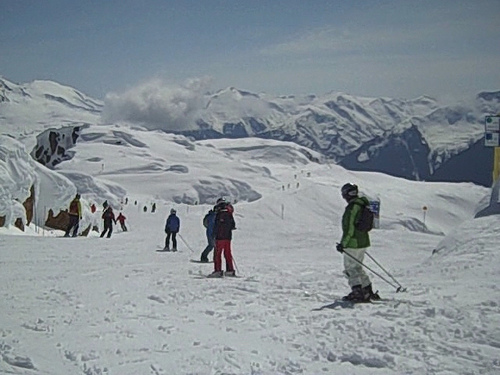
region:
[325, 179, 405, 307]
snow skier standing facing left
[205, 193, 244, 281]
skier with red pants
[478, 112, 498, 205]
sign on yellow pole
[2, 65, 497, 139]
tops of distant snowy mountains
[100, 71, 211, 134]
cloud on distant mountain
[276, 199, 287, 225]
snow trail marker stick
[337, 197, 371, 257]
two toned green winter jacket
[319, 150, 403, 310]
skier with a green suit on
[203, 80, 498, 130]
snow covered mountain range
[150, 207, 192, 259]
skier with a blue jacket on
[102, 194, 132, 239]
two skiers coming down the hill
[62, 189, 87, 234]
skier in yellow jacket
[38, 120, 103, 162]
white snow melting on side of mountain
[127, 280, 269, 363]
snow tracks from skiers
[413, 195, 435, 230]
ski lift monitor on the snow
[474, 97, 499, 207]
sign on the distance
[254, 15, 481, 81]
clouds in the sky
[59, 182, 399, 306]
skiers on the mountain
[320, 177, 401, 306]
skier wearing white pants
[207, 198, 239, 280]
skier wearing dark pink pants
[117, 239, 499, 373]
tracks in the snow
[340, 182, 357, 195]
helmet skier is wearing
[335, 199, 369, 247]
two tone green jacket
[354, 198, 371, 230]
backpack skier is wearing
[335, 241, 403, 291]
black ski poles skier is holding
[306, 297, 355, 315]
shadow on the snow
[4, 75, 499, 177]
mountains in the distance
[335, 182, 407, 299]
skier in a green jacket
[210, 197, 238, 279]
skier wearing red snowpants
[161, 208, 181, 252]
a skier wearing a blue jacket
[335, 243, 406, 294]
a skier's ski poles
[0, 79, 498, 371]
snow covered mountain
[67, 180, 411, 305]
group of skiers going down a hill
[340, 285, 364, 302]
a skier's left boot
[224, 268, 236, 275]
a skier's right boot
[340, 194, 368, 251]
The green coat the skier is wearing.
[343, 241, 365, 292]
The white pants the skier is wearing.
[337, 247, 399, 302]
The ski poles in the skier's hands on the right.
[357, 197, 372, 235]
The back pack the skier in the green coat is carrying.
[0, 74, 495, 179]
The snow covered mountains in the distance.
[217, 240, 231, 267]
The red pants the skier is wearing.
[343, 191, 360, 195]
The snow goggles the skier in the green jacket is wearing.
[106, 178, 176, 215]
The people in the distance.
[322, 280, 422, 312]
The skis the skier in the green coat is standing on.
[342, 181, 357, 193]
The helmet the skier in the green coat is wearing.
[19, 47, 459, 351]
Snow laden mountain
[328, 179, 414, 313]
A skier on the mountain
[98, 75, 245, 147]
Snow blast in the background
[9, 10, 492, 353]
Cold winter on the mountain top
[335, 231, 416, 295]
Ski poles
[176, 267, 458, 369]
Tracks on the snow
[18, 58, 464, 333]
skiers at top of snowy mountain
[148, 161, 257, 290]
group of skiers standing on mountain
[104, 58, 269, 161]
low white cloud on snowy mountain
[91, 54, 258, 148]
low cloud on top of mountain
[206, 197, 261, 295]
skier wearing red pants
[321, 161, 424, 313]
skier wearing green jacket and black helmet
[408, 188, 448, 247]
flag for skiers on mountain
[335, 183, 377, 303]
skier wearing white pants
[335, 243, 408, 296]
skier holding ski poles